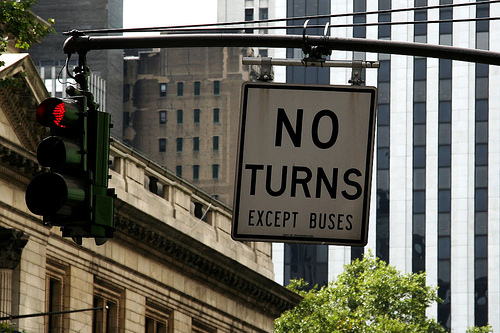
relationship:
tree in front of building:
[269, 253, 453, 330] [8, 0, 498, 316]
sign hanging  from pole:
[228, 77, 380, 247] [112, 23, 446, 75]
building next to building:
[9, 2, 124, 150] [124, 23, 260, 242]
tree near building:
[1, 4, 53, 52] [0, 50, 302, 332]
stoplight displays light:
[22, 84, 118, 249] [31, 92, 84, 138]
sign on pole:
[231, 77, 376, 247] [130, 19, 446, 81]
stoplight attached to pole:
[21, 26, 124, 247] [61, 28, 498, 64]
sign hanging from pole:
[231, 77, 376, 247] [65, 30, 498, 67]